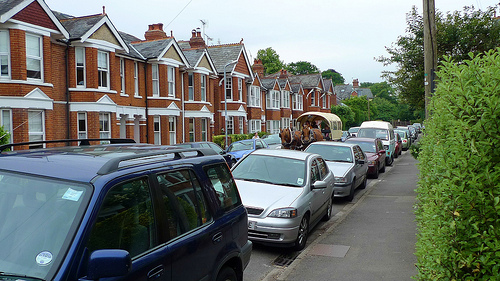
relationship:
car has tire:
[213, 144, 340, 251] [321, 191, 339, 224]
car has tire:
[213, 144, 340, 251] [289, 212, 314, 254]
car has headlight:
[213, 144, 340, 251] [266, 203, 298, 222]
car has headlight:
[301, 140, 373, 202] [330, 174, 348, 188]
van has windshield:
[358, 118, 402, 165] [358, 124, 391, 141]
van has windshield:
[0, 134, 258, 279] [0, 168, 96, 280]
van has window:
[0, 134, 258, 279] [201, 159, 246, 215]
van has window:
[0, 134, 258, 279] [155, 162, 217, 248]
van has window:
[0, 134, 258, 279] [69, 173, 166, 280]